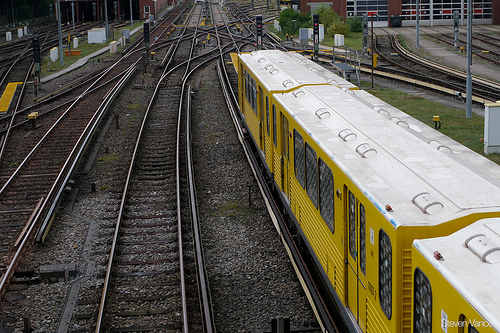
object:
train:
[227, 48, 499, 332]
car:
[237, 35, 360, 174]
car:
[265, 84, 499, 333]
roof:
[235, 46, 499, 332]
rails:
[0, 0, 55, 30]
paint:
[0, 81, 23, 112]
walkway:
[0, 82, 27, 114]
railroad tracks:
[94, 0, 205, 332]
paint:
[319, 159, 334, 234]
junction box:
[143, 22, 150, 43]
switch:
[154, 36, 159, 60]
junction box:
[32, 36, 41, 63]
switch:
[33, 75, 37, 100]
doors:
[345, 187, 368, 332]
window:
[318, 157, 337, 234]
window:
[291, 128, 305, 188]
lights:
[257, 28, 261, 31]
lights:
[315, 29, 319, 32]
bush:
[326, 22, 352, 37]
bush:
[276, 7, 308, 35]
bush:
[346, 13, 368, 33]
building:
[291, 0, 498, 29]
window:
[348, 12, 354, 16]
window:
[367, 1, 379, 6]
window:
[357, 11, 368, 16]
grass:
[317, 32, 367, 52]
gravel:
[0, 0, 187, 295]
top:
[237, 49, 500, 333]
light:
[257, 24, 261, 28]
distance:
[0, 0, 500, 122]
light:
[315, 23, 319, 26]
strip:
[0, 81, 23, 111]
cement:
[0, 81, 26, 114]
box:
[483, 104, 500, 155]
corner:
[303, 68, 499, 325]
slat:
[297, 54, 494, 105]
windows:
[347, 189, 358, 262]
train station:
[292, 0, 500, 37]